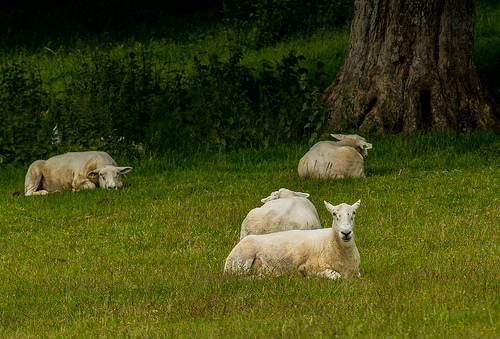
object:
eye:
[352, 211, 355, 215]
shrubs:
[0, 7, 499, 156]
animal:
[222, 199, 364, 281]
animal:
[238, 188, 321, 241]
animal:
[298, 134, 373, 178]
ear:
[323, 200, 334, 212]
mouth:
[105, 183, 117, 189]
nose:
[108, 183, 117, 189]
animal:
[23, 151, 132, 196]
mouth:
[341, 234, 353, 242]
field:
[0, 28, 499, 339]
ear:
[350, 199, 362, 208]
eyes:
[332, 212, 337, 217]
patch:
[4, 130, 494, 339]